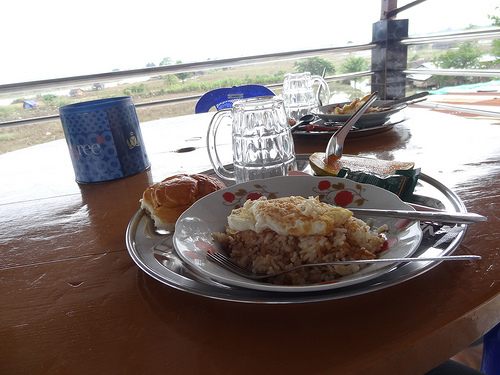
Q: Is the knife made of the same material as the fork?
A: Yes, both the knife and the fork are made of metal.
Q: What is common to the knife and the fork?
A: The material, both the knife and the fork are metallic.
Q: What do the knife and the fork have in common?
A: The material, both the knife and the fork are metallic.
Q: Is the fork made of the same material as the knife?
A: Yes, both the fork and the knife are made of metal.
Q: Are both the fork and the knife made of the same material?
A: Yes, both the fork and the knife are made of metal.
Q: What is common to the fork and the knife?
A: The material, both the fork and the knife are metallic.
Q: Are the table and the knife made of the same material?
A: No, the table is made of wood and the knife is made of metal.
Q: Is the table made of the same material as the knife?
A: No, the table is made of wood and the knife is made of metal.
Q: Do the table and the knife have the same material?
A: No, the table is made of wood and the knife is made of metal.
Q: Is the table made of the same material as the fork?
A: No, the table is made of wood and the fork is made of metal.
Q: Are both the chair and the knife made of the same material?
A: No, the chair is made of plastic and the knife is made of metal.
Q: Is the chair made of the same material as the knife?
A: No, the chair is made of plastic and the knife is made of metal.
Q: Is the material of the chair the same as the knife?
A: No, the chair is made of plastic and the knife is made of metal.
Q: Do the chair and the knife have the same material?
A: No, the chair is made of plastic and the knife is made of metal.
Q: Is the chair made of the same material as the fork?
A: No, the chair is made of plastic and the fork is made of metal.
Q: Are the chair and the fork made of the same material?
A: No, the chair is made of plastic and the fork is made of metal.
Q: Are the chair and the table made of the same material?
A: No, the chair is made of plastic and the table is made of wood.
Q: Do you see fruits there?
A: Yes, there is a fruit.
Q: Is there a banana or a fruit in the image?
A: Yes, there is a fruit.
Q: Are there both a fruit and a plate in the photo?
A: Yes, there are both a fruit and a plate.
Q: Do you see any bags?
A: No, there are no bags.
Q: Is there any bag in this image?
A: No, there are no bags.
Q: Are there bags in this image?
A: No, there are no bags.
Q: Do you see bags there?
A: No, there are no bags.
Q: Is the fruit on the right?
A: Yes, the fruit is on the right of the image.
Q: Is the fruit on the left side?
A: No, the fruit is on the right of the image.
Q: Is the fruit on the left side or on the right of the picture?
A: The fruit is on the right of the image.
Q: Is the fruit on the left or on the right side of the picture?
A: The fruit is on the right of the image.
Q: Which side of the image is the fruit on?
A: The fruit is on the right of the image.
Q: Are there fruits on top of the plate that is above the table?
A: Yes, there is a fruit on top of the plate.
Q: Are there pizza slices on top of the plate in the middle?
A: No, there is a fruit on top of the plate.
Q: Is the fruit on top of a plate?
A: Yes, the fruit is on top of a plate.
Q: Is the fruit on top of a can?
A: No, the fruit is on top of a plate.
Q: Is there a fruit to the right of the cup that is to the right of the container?
A: Yes, there is a fruit to the right of the cup.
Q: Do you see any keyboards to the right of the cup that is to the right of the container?
A: No, there is a fruit to the right of the cup.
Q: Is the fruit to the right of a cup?
A: Yes, the fruit is to the right of a cup.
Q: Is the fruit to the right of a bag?
A: No, the fruit is to the right of a cup.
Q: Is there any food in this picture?
A: Yes, there is food.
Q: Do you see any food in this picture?
A: Yes, there is food.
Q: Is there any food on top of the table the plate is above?
A: Yes, there is food on top of the table.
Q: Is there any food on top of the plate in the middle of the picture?
A: Yes, there is food on top of the plate.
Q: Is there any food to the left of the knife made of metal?
A: Yes, there is food to the left of the knife.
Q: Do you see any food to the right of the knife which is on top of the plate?
A: No, the food is to the left of the knife.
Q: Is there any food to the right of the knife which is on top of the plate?
A: No, the food is to the left of the knife.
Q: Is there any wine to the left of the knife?
A: No, there is food to the left of the knife.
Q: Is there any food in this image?
A: Yes, there is food.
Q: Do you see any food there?
A: Yes, there is food.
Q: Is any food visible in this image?
A: Yes, there is food.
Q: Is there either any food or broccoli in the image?
A: Yes, there is food.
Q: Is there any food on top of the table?
A: Yes, there is food on top of the table.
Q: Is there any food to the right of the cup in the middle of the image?
A: Yes, there is food to the right of the cup.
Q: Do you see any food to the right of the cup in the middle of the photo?
A: Yes, there is food to the right of the cup.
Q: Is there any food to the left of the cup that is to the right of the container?
A: No, the food is to the right of the cup.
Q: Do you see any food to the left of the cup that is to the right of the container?
A: No, the food is to the right of the cup.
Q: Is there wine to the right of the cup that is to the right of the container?
A: No, there is food to the right of the cup.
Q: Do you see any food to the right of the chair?
A: Yes, there is food to the right of the chair.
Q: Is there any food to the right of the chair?
A: Yes, there is food to the right of the chair.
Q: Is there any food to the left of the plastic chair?
A: No, the food is to the right of the chair.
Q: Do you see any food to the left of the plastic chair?
A: No, the food is to the right of the chair.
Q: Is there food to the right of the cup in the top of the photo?
A: Yes, there is food to the right of the cup.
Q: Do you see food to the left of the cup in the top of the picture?
A: No, the food is to the right of the cup.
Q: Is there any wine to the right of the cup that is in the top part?
A: No, there is food to the right of the cup.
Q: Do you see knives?
A: Yes, there is a knife.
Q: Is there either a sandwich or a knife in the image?
A: Yes, there is a knife.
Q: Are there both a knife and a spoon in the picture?
A: Yes, there are both a knife and a spoon.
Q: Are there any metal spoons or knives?
A: Yes, there is a metal knife.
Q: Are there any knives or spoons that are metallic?
A: Yes, the knife is metallic.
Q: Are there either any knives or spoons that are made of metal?
A: Yes, the knife is made of metal.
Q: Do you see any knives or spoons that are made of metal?
A: Yes, the knife is made of metal.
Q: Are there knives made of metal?
A: Yes, there is a knife that is made of metal.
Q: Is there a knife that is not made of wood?
A: Yes, there is a knife that is made of metal.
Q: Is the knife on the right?
A: Yes, the knife is on the right of the image.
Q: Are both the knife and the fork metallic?
A: Yes, both the knife and the fork are metallic.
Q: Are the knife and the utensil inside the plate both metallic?
A: Yes, both the knife and the fork are metallic.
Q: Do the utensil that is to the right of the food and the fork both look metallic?
A: Yes, both the knife and the fork are metallic.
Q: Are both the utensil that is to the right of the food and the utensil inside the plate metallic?
A: Yes, both the knife and the fork are metallic.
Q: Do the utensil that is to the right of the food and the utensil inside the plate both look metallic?
A: Yes, both the knife and the fork are metallic.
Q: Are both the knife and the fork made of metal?
A: Yes, both the knife and the fork are made of metal.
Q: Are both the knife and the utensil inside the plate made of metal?
A: Yes, both the knife and the fork are made of metal.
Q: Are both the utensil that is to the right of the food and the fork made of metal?
A: Yes, both the knife and the fork are made of metal.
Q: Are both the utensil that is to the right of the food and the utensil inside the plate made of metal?
A: Yes, both the knife and the fork are made of metal.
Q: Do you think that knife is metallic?
A: Yes, the knife is metallic.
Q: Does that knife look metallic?
A: Yes, the knife is metallic.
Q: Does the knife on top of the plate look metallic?
A: Yes, the knife is metallic.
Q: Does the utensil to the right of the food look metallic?
A: Yes, the knife is metallic.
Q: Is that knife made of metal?
A: Yes, the knife is made of metal.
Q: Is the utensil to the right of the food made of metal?
A: Yes, the knife is made of metal.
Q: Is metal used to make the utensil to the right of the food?
A: Yes, the knife is made of metal.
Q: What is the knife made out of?
A: The knife is made of metal.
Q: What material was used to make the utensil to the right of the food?
A: The knife is made of metal.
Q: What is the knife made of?
A: The knife is made of metal.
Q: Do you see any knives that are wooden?
A: No, there is a knife but it is metallic.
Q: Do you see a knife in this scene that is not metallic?
A: No, there is a knife but it is metallic.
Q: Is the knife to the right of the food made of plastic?
A: No, the knife is made of metal.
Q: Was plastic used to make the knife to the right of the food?
A: No, the knife is made of metal.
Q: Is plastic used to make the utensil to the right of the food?
A: No, the knife is made of metal.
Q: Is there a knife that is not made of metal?
A: No, there is a knife but it is made of metal.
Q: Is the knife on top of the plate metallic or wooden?
A: The knife is metallic.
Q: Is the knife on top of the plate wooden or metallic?
A: The knife is metallic.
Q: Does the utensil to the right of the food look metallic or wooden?
A: The knife is metallic.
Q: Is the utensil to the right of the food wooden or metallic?
A: The knife is metallic.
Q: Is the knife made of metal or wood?
A: The knife is made of metal.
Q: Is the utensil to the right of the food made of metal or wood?
A: The knife is made of metal.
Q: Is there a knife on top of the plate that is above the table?
A: Yes, there is a knife on top of the plate.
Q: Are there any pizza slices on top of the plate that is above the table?
A: No, there is a knife on top of the plate.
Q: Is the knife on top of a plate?
A: Yes, the knife is on top of a plate.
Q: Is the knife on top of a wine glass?
A: No, the knife is on top of a plate.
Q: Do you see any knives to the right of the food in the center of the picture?
A: Yes, there is a knife to the right of the food.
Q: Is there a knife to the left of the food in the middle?
A: No, the knife is to the right of the food.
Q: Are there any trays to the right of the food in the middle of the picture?
A: No, there is a knife to the right of the food.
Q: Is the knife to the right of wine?
A: No, the knife is to the right of the food.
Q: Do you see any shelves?
A: No, there are no shelves.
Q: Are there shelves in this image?
A: No, there are no shelves.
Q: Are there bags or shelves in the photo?
A: No, there are no shelves or bags.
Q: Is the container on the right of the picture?
A: No, the container is on the left of the image.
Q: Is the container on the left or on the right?
A: The container is on the left of the image.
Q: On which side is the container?
A: The container is on the left of the image.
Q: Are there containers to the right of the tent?
A: Yes, there is a container to the right of the tent.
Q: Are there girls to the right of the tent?
A: No, there is a container to the right of the tent.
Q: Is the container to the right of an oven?
A: No, the container is to the right of a tent.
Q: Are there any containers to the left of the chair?
A: Yes, there is a container to the left of the chair.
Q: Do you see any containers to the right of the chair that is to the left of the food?
A: No, the container is to the left of the chair.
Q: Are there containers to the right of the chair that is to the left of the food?
A: No, the container is to the left of the chair.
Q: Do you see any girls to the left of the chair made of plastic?
A: No, there is a container to the left of the chair.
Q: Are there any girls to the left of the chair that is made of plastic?
A: No, there is a container to the left of the chair.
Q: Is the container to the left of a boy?
A: No, the container is to the left of a chair.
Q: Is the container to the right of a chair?
A: No, the container is to the left of a chair.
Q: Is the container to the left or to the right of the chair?
A: The container is to the left of the chair.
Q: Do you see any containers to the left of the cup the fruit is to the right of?
A: Yes, there is a container to the left of the cup.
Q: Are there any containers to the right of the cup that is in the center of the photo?
A: No, the container is to the left of the cup.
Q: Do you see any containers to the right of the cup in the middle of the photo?
A: No, the container is to the left of the cup.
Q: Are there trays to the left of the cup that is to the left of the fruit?
A: No, there is a container to the left of the cup.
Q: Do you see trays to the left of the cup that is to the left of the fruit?
A: No, there is a container to the left of the cup.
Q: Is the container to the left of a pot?
A: No, the container is to the left of the cup.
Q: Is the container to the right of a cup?
A: No, the container is to the left of a cup.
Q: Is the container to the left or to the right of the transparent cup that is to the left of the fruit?
A: The container is to the left of the cup.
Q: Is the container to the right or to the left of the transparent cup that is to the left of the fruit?
A: The container is to the left of the cup.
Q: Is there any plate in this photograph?
A: Yes, there is a plate.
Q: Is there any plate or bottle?
A: Yes, there is a plate.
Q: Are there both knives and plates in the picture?
A: Yes, there are both a plate and a knife.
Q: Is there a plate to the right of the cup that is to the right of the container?
A: Yes, there is a plate to the right of the cup.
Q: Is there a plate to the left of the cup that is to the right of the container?
A: No, the plate is to the right of the cup.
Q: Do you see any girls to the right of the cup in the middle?
A: No, there is a plate to the right of the cup.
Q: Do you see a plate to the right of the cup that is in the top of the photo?
A: Yes, there is a plate to the right of the cup.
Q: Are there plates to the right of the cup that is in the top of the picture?
A: Yes, there is a plate to the right of the cup.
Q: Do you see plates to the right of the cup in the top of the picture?
A: Yes, there is a plate to the right of the cup.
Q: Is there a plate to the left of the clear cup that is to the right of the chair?
A: No, the plate is to the right of the cup.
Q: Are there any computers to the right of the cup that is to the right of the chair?
A: No, there is a plate to the right of the cup.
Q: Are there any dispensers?
A: No, there are no dispensers.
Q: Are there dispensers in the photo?
A: No, there are no dispensers.